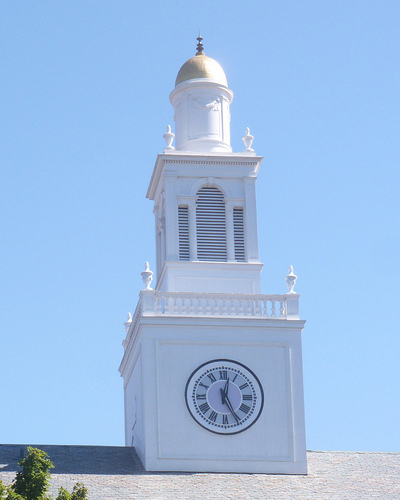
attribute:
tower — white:
[119, 9, 313, 474]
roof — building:
[130, 144, 267, 199]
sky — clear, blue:
[301, 19, 391, 205]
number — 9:
[194, 389, 208, 404]